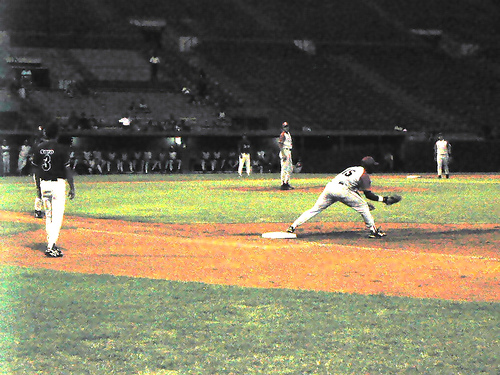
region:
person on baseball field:
[279, 153, 411, 239]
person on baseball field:
[30, 115, 82, 267]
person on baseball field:
[270, 114, 305, 189]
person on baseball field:
[230, 130, 257, 177]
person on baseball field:
[427, 128, 454, 179]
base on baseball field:
[259, 225, 298, 242]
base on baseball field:
[404, 170, 426, 181]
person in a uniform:
[269, 117, 306, 189]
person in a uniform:
[284, 148, 404, 238]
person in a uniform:
[31, 118, 80, 262]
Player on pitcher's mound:
[274, 117, 299, 190]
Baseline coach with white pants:
[34, 119, 75, 259]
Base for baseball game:
[253, 227, 301, 242]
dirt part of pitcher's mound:
[220, 185, 266, 190]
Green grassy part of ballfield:
[101, 307, 220, 347]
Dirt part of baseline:
[118, 241, 190, 269]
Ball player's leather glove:
[378, 192, 404, 208]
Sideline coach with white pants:
[235, 130, 256, 178]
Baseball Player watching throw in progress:
[431, 131, 453, 180]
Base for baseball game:
[401, 174, 425, 181]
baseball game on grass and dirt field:
[18, 15, 485, 312]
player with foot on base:
[260, 151, 397, 241]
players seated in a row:
[57, 135, 237, 170]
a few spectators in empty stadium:
[2, 6, 492, 136]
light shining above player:
[160, 127, 185, 172]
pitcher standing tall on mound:
[260, 115, 300, 192]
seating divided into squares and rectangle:
[0, 25, 225, 130]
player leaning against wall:
[15, 131, 30, 172]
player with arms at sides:
[26, 115, 76, 255]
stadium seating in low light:
[230, 5, 491, 127]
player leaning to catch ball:
[293, 146, 398, 243]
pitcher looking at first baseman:
[271, 110, 296, 188]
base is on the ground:
[249, 219, 309, 248]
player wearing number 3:
[27, 116, 63, 266]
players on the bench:
[60, 149, 240, 174]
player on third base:
[425, 121, 457, 186]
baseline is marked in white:
[89, 223, 499, 273]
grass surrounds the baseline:
[2, 281, 442, 370]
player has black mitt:
[382, 190, 409, 220]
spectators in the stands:
[5, 36, 217, 137]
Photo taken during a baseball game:
[6, 8, 490, 361]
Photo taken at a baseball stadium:
[13, 8, 485, 365]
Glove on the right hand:
[382, 193, 409, 210]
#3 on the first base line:
[30, 106, 90, 268]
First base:
[259, 220, 304, 241]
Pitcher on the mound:
[260, 118, 309, 195]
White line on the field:
[30, 188, 487, 263]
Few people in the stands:
[27, 38, 461, 138]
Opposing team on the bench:
[26, 144, 289, 174]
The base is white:
[233, 213, 313, 243]